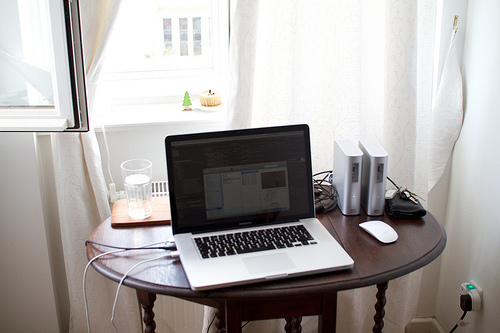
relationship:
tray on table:
[109, 191, 174, 228] [85, 197, 445, 331]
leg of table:
[373, 278, 390, 330] [95, 217, 445, 331]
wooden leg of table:
[82, 184, 459, 328] [85, 197, 445, 331]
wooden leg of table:
[218, 310, 245, 330] [85, 197, 445, 331]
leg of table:
[282, 295, 305, 332] [84, 183, 445, 300]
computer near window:
[164, 123, 354, 293] [0, 3, 242, 137]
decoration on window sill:
[201, 87, 222, 104] [91, 93, 232, 129]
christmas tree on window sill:
[181, 91, 193, 112] [91, 93, 232, 129]